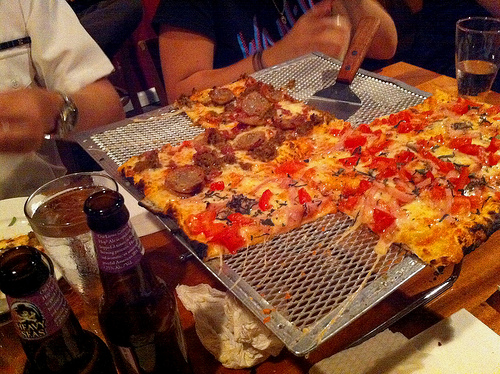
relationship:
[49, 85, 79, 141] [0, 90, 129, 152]
wrist watch on arm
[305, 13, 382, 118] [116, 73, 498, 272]
spatula for serving pizza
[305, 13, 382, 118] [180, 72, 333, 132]
spatula under pizza